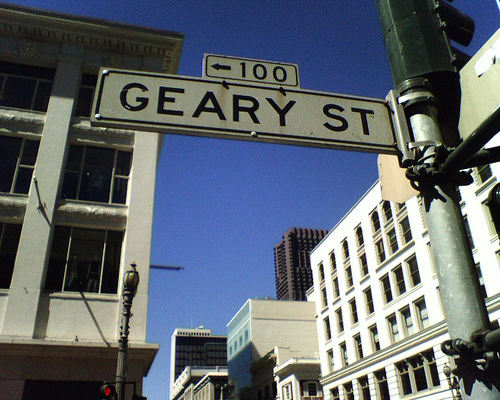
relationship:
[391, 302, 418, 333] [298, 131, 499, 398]
window on building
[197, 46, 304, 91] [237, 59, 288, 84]
sign with numbers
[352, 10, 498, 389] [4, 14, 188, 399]
pole in front of building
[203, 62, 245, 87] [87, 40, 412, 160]
arrow on sign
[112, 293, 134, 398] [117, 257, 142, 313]
pole with street lamp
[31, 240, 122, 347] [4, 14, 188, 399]
shadow on building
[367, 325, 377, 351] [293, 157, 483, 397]
window on building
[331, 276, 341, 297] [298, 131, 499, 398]
window on building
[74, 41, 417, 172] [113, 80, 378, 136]
sign with lettering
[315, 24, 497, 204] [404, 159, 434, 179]
electric signal with bolts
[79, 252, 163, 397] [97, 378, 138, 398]
light on signal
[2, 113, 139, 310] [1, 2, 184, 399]
windows on white building